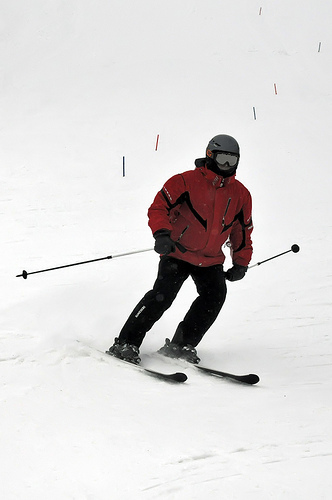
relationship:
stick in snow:
[120, 155, 128, 179] [1, 4, 331, 500]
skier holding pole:
[111, 135, 251, 367] [15, 245, 170, 278]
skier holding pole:
[111, 135, 251, 367] [235, 243, 302, 275]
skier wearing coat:
[111, 135, 251, 367] [147, 168, 254, 267]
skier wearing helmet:
[111, 135, 251, 367] [205, 134, 243, 159]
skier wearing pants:
[111, 135, 251, 367] [116, 254, 227, 347]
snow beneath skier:
[1, 4, 331, 500] [111, 135, 251, 367]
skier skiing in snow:
[111, 135, 251, 367] [1, 4, 331, 500]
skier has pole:
[111, 135, 251, 367] [15, 245, 170, 278]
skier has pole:
[111, 135, 251, 367] [235, 243, 302, 275]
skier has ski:
[111, 135, 251, 367] [141, 347, 261, 386]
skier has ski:
[111, 135, 251, 367] [56, 336, 188, 388]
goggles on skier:
[213, 149, 241, 168] [111, 135, 251, 367]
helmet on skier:
[205, 134, 243, 159] [111, 135, 251, 367]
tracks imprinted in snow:
[0, 330, 109, 364] [1, 4, 331, 500]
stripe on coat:
[166, 189, 205, 228] [147, 168, 254, 267]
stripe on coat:
[222, 209, 246, 250] [147, 168, 254, 267]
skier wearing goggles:
[111, 135, 251, 367] [213, 149, 241, 168]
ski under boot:
[141, 347, 261, 386] [160, 336, 199, 364]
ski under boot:
[56, 336, 188, 388] [109, 341, 142, 364]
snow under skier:
[1, 4, 331, 500] [111, 135, 251, 367]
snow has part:
[1, 4, 331, 500] [20, 26, 103, 127]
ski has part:
[141, 347, 261, 386] [227, 367, 258, 386]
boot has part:
[109, 341, 142, 364] [111, 341, 121, 357]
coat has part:
[147, 168, 254, 267] [200, 187, 230, 225]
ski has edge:
[141, 347, 261, 386] [202, 366, 243, 374]